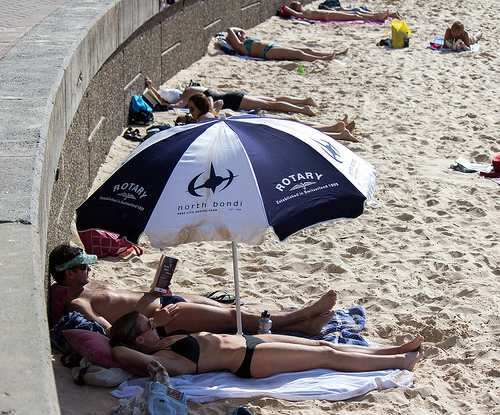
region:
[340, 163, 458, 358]
the sand is clear and visible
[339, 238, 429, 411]
the sand is clear and visible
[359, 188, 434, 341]
the sand is clear and visible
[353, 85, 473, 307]
the sand is clear and visible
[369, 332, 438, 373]
Feet are crossed.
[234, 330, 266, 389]
A black bikini bottle.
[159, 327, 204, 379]
A black bikini top.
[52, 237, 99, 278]
A green visor.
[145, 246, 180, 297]
A book.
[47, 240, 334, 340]
The man reads a book.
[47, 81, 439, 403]
hey lounge under a beach umbrella.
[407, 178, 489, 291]
Feet prints in the beach sand.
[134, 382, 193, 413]
A pair of jeans on the beach.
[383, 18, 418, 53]
A yellow bag in the sand.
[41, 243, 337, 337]
a man laying on sand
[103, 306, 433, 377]
a woman laying on beach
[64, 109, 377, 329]
a large blue and white umbrella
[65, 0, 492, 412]
a light brown sandy beach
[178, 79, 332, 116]
a person sun tanning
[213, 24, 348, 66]
a person sun tanning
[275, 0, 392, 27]
a person sun tanning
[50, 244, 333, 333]
a man wearing a speedo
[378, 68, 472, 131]
foot prints in sand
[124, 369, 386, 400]
a white beach blanket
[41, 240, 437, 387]
Man and woman sunbathing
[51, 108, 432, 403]
Man and woman under beach umbrella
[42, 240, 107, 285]
Man wearing a visor on his head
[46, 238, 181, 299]
Man reading a book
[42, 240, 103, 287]
Man wearing sunglasses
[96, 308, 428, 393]
Woman laying on a beach towel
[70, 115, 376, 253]
Blue and white beach umbrella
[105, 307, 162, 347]
Woman wearing sunglasses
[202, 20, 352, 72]
Person enjoying the beach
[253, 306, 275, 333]
Top of a drink bottle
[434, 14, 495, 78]
a person sunbathing at the beach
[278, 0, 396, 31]
a person sunbathing at the beach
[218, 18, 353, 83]
a person sunbathing at the beach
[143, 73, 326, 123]
a person sunbathing at the beach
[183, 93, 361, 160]
a person sunbathing at the beach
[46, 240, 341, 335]
a person sunbathing at the beach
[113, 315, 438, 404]
a person sunbathing at the beach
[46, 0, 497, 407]
people sunbathing at the beach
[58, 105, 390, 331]
this is an umbrella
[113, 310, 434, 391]
the lady is wearing a bikini